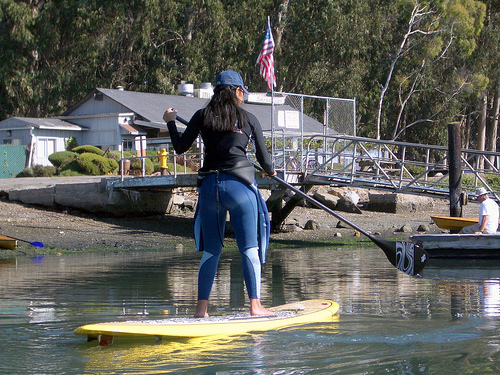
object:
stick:
[167, 107, 275, 301]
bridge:
[112, 129, 499, 206]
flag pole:
[267, 16, 274, 169]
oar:
[6, 235, 44, 248]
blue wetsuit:
[197, 173, 260, 300]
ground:
[0, 172, 447, 258]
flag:
[255, 24, 277, 90]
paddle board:
[72, 298, 341, 346]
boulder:
[368, 191, 436, 215]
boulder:
[314, 186, 362, 214]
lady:
[162, 70, 277, 319]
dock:
[0, 176, 479, 256]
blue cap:
[211, 69, 249, 95]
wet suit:
[192, 160, 270, 264]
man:
[458, 187, 500, 235]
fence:
[270, 64, 355, 171]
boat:
[408, 215, 500, 260]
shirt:
[166, 107, 274, 175]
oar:
[171, 108, 429, 276]